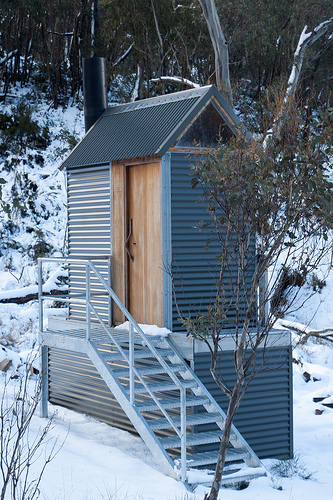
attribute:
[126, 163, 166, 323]
door — brown, wood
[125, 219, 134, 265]
handle — curved, brown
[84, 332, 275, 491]
stairs — grey, blue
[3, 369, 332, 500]
ground — white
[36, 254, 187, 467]
rail — metal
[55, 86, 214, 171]
roof — dark grey, black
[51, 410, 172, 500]
snow — white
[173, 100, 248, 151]
window — glass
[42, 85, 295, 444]
cabin — small, blue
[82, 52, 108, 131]
chimney — black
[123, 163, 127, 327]
door trim — aluminum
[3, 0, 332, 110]
trees — brown, barren